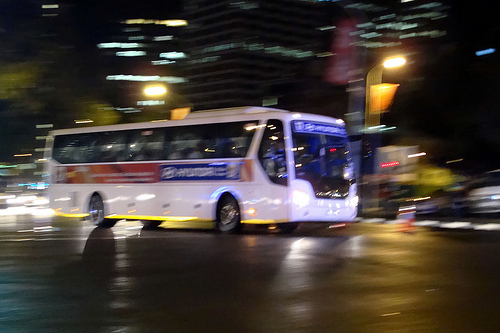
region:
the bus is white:
[88, 81, 250, 257]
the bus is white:
[125, 67, 293, 296]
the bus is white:
[39, 58, 394, 278]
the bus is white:
[168, 110, 430, 323]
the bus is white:
[153, 80, 271, 185]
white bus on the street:
[37, 102, 382, 236]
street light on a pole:
[365, 47, 415, 90]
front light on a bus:
[284, 189, 320, 214]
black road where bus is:
[14, 242, 453, 322]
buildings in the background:
[158, 12, 348, 86]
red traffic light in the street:
[379, 157, 401, 169]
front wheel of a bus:
[207, 189, 249, 234]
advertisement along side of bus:
[47, 157, 255, 189]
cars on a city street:
[395, 152, 498, 234]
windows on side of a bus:
[52, 120, 261, 167]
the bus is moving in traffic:
[40, 107, 361, 255]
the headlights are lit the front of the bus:
[293, 179, 360, 224]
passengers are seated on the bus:
[54, 127, 255, 168]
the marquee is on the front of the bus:
[283, 112, 350, 139]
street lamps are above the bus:
[131, 51, 411, 224]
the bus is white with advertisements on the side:
[42, 105, 357, 234]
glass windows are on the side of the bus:
[47, 120, 289, 183]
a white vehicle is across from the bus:
[466, 167, 499, 219]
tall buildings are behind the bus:
[12, 4, 499, 178]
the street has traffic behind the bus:
[5, 180, 499, 328]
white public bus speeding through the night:
[31, 114, 373, 229]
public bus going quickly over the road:
[40, 109, 365, 236]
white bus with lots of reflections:
[37, 107, 376, 244]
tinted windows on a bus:
[47, 116, 265, 164]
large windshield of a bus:
[283, 108, 359, 211]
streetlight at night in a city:
[360, 45, 402, 218]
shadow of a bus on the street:
[45, 231, 376, 316]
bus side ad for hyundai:
[49, 160, 268, 187]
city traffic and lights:
[3, 159, 40, 233]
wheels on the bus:
[210, 194, 255, 235]